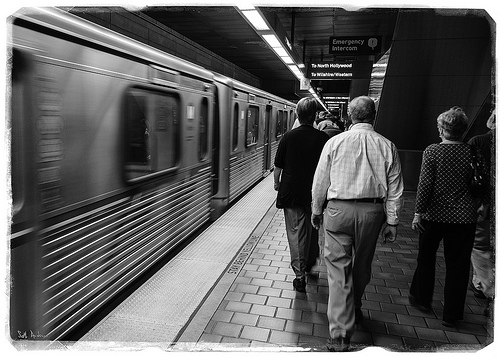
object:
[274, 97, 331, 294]
person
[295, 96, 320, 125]
head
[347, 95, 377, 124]
head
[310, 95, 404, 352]
man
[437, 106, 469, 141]
head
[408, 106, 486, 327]
woman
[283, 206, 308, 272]
leg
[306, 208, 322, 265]
leg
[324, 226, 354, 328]
leg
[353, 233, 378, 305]
leg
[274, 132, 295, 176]
arm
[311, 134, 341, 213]
arm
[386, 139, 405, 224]
arm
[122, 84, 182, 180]
window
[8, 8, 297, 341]
train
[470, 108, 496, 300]
woman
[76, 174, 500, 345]
zone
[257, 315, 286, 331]
tile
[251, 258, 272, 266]
tile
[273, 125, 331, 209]
shirt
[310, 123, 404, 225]
shirt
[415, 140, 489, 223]
shirt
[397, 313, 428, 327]
brick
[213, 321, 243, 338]
tile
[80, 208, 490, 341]
floor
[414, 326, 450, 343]
tile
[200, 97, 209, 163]
window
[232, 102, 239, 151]
window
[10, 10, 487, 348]
station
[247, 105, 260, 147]
window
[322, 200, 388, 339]
pants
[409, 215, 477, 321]
pants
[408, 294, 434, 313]
shoe